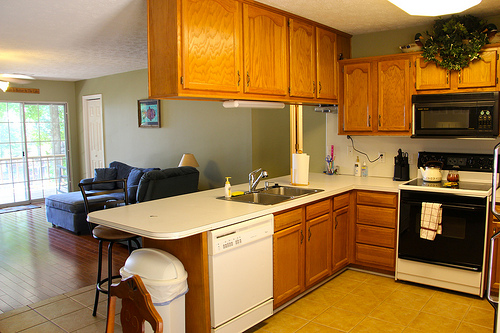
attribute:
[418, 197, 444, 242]
dish towel — hanging, white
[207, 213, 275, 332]
dishwasher — white, ew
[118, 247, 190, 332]
trashcan — white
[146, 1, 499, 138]
cabinets — brown, wooden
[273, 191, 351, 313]
cabinets — wooden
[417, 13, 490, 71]
plant — green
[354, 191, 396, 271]
drawers — wooden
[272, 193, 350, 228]
drawers — wooden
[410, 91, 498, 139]
microwave — black, mounted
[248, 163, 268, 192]
faucet — stailess steel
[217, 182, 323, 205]
sink — double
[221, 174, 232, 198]
soap bottle — pump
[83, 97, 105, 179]
door — closed, white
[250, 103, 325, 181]
wall — yellow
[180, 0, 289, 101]
cabinet — wooden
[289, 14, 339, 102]
cabinet — wooden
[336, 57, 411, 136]
cabinet — wooden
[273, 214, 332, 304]
cabinet — wooden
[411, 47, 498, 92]
cabinet — wooden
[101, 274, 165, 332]
chair — wooden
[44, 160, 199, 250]
couch — grey, empt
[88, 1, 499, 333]
kitchen — room, empt, clea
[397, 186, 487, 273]
oven door — black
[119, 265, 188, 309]
bag — white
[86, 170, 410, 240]
counter — bare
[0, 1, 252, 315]
livig room — empt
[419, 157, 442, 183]
tea kettle — white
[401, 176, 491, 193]
stove — electric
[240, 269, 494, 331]
floor — ice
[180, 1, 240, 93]
cabinet door — wood, brow, brown wood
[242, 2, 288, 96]
cabinet door — wood, brow, brown wood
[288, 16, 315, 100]
cabinet door — wood, brow, brown wood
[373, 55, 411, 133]
cabinet door — wood, brow, brown wood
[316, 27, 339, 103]
cabinet door — wood, brow, brown wood